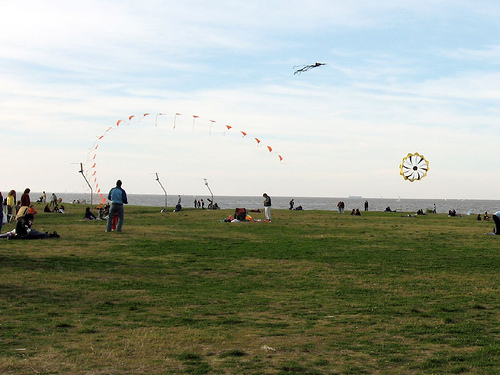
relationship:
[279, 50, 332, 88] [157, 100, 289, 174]
kite with tassels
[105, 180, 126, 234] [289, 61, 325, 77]
man flying a kite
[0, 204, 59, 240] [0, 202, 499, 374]
people sitting on a lake front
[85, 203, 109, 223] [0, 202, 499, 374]
people sitting on a lake front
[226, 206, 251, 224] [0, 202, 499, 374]
people sitting on a lake front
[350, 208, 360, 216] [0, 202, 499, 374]
people sitting on a lake front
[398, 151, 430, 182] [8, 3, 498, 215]
kite flying in sky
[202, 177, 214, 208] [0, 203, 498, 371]
pole sticking out of ground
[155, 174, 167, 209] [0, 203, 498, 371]
pole sticking out of ground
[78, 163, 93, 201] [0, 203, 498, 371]
pole sticking out of ground